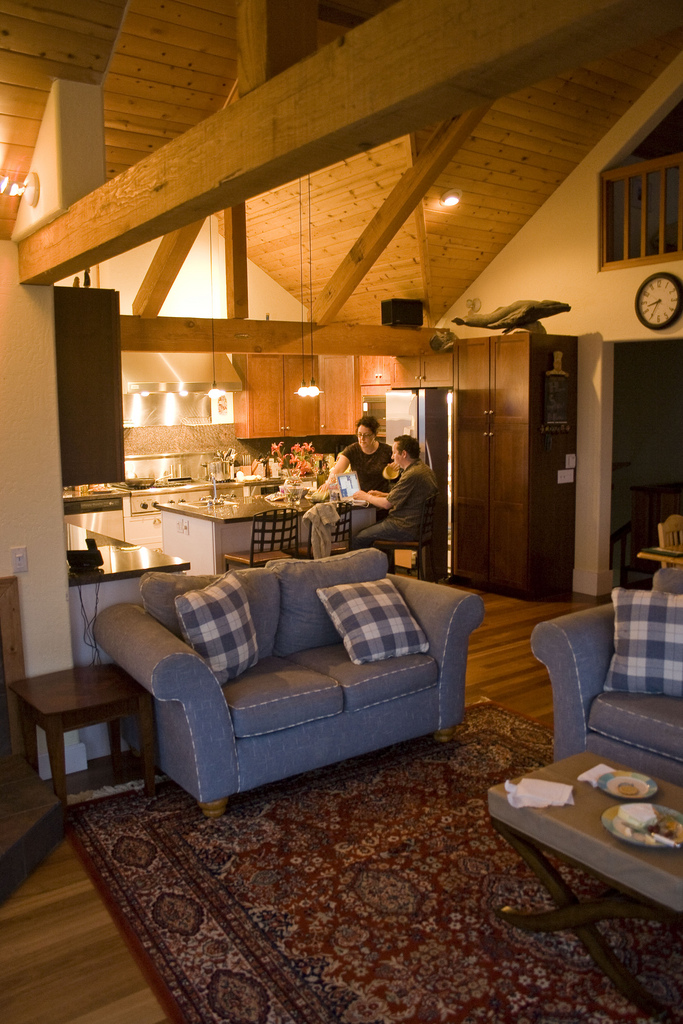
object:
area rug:
[66, 695, 682, 1021]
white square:
[347, 597, 368, 615]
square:
[226, 610, 243, 632]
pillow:
[174, 569, 260, 687]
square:
[205, 586, 228, 601]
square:
[224, 574, 242, 591]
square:
[185, 591, 207, 610]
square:
[335, 602, 354, 623]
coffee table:
[488, 751, 683, 1023]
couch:
[530, 569, 682, 789]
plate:
[597, 770, 682, 847]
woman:
[318, 416, 400, 493]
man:
[352, 435, 438, 551]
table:
[8, 661, 157, 813]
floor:
[0, 587, 683, 1024]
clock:
[635, 272, 682, 330]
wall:
[431, 56, 682, 597]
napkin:
[504, 778, 575, 809]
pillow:
[316, 578, 430, 665]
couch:
[92, 547, 485, 819]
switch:
[11, 545, 28, 572]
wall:
[0, 240, 88, 781]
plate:
[597, 769, 659, 799]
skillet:
[396, 573, 613, 725]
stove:
[386, 387, 454, 576]